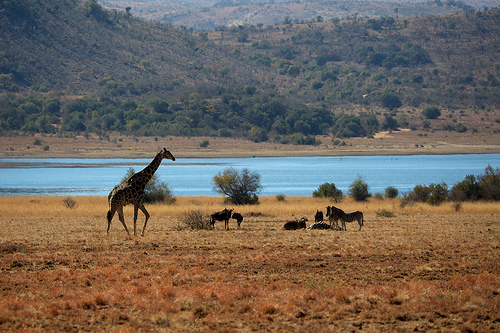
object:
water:
[0, 153, 500, 196]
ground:
[0, 196, 500, 333]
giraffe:
[103, 147, 177, 239]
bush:
[276, 193, 286, 201]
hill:
[0, 0, 499, 134]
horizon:
[0, 193, 497, 198]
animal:
[230, 212, 244, 230]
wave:
[0, 160, 238, 170]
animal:
[281, 216, 310, 230]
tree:
[253, 136, 261, 143]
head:
[162, 147, 176, 161]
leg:
[138, 203, 151, 238]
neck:
[140, 154, 163, 185]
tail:
[103, 192, 113, 227]